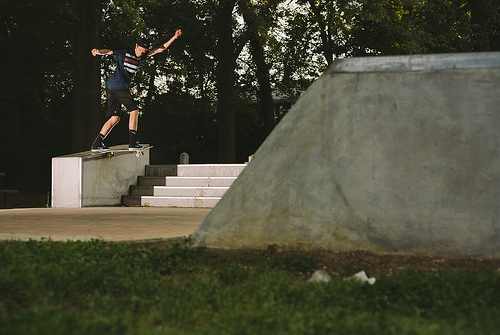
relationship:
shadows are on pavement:
[89, 143, 194, 211] [110, 164, 181, 224]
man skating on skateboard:
[91, 29, 182, 152] [91, 146, 153, 158]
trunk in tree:
[219, 76, 240, 161] [209, 14, 241, 162]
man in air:
[91, 29, 182, 152] [0, 81, 62, 140]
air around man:
[0, 81, 62, 140] [91, 29, 182, 152]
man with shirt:
[91, 29, 182, 152] [103, 42, 152, 93]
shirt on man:
[103, 42, 152, 93] [91, 29, 182, 152]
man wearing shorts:
[91, 29, 182, 152] [106, 87, 140, 117]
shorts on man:
[106, 87, 140, 117] [91, 29, 182, 152]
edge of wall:
[78, 157, 84, 163] [53, 158, 82, 209]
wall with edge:
[53, 158, 82, 209] [78, 157, 84, 163]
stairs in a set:
[119, 164, 247, 210] [171, 159, 204, 222]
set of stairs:
[171, 159, 204, 222] [119, 164, 247, 210]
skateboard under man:
[92, 143, 152, 155] [90, 25, 186, 150]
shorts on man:
[97, 81, 142, 118] [91, 29, 182, 152]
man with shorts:
[91, 29, 182, 152] [97, 81, 142, 118]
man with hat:
[76, 22, 183, 143] [130, 31, 150, 48]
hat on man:
[130, 31, 150, 48] [76, 22, 183, 143]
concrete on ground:
[279, 53, 496, 274] [98, 248, 267, 335]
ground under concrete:
[98, 248, 267, 335] [279, 53, 496, 274]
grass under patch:
[93, 239, 241, 333] [89, 260, 221, 335]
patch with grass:
[89, 260, 221, 335] [93, 239, 241, 333]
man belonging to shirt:
[91, 29, 182, 152] [103, 47, 154, 96]